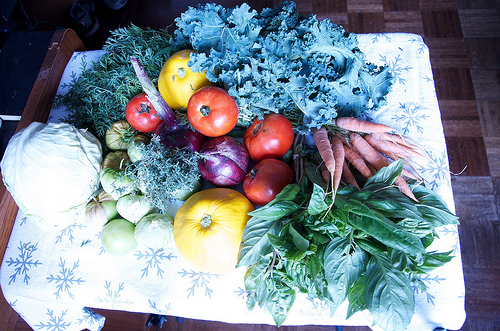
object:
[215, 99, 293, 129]
group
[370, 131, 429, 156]
carrots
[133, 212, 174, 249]
tomatillos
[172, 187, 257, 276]
squash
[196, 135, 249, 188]
onions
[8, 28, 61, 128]
object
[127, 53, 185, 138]
vegetable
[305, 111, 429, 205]
bunch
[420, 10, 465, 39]
squares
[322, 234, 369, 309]
leaves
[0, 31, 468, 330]
table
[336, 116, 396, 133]
carrot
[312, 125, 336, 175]
carrot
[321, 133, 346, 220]
carrot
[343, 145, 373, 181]
carrot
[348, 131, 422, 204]
carrot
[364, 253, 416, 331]
greens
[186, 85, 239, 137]
tomato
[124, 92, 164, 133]
tomato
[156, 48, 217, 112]
vegetable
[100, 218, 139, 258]
vegetable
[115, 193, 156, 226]
vegetable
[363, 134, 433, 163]
carrots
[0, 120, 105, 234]
cabbage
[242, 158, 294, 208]
tomato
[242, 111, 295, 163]
tomato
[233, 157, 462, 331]
spinach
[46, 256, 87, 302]
snowflakes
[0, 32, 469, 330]
tablecloth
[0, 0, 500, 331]
floor